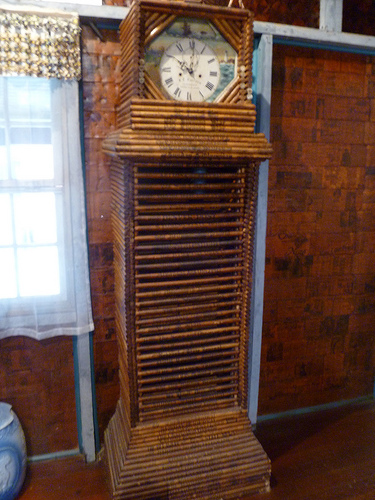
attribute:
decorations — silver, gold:
[0, 10, 81, 79]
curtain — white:
[1, 5, 96, 339]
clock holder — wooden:
[99, 1, 275, 499]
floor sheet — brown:
[266, 415, 371, 496]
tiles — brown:
[293, 87, 351, 166]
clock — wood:
[89, 3, 273, 499]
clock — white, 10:
[160, 39, 219, 102]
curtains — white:
[0, 9, 98, 334]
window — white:
[0, 64, 67, 201]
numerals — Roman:
[161, 37, 225, 98]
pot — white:
[0, 400, 29, 498]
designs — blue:
[1, 439, 31, 496]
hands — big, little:
[167, 48, 202, 76]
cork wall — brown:
[278, 50, 365, 303]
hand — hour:
[169, 56, 188, 75]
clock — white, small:
[156, 35, 225, 101]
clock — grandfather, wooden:
[154, 14, 278, 290]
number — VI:
[186, 91, 192, 100]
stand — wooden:
[93, 2, 281, 499]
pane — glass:
[17, 249, 64, 293]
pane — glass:
[0, 251, 19, 293]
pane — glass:
[13, 184, 59, 241]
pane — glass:
[0, 191, 15, 238]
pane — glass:
[7, 122, 54, 180]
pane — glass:
[0, 132, 10, 179]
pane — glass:
[7, 76, 56, 124]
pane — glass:
[0, 79, 14, 120]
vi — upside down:
[185, 90, 193, 103]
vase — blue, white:
[0, 401, 34, 488]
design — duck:
[142, 40, 167, 69]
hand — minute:
[191, 45, 197, 77]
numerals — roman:
[186, 36, 194, 48]